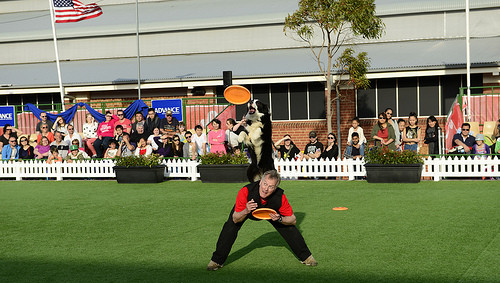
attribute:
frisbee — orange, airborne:
[221, 81, 258, 117]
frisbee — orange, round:
[222, 80, 255, 112]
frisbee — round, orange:
[251, 204, 281, 230]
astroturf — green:
[0, 178, 495, 280]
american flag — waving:
[55, 1, 104, 23]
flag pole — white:
[47, 3, 71, 116]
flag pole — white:
[48, 2, 73, 110]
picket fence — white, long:
[7, 156, 494, 179]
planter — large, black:
[108, 165, 167, 183]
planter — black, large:
[191, 164, 256, 179]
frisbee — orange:
[223, 79, 253, 111]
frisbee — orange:
[327, 201, 356, 214]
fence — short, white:
[6, 151, 499, 181]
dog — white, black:
[231, 94, 275, 177]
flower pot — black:
[364, 157, 427, 182]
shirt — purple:
[37, 140, 49, 153]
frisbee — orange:
[244, 202, 281, 223]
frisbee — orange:
[328, 203, 351, 216]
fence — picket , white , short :
[4, 156, 489, 184]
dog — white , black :
[235, 92, 276, 166]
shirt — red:
[231, 179, 285, 217]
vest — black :
[244, 186, 284, 221]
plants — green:
[114, 156, 171, 184]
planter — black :
[105, 158, 165, 181]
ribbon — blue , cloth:
[15, 103, 155, 120]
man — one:
[456, 118, 475, 152]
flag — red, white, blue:
[39, 0, 118, 48]